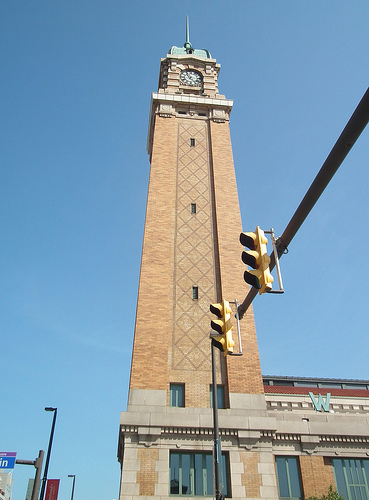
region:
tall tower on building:
[111, 8, 367, 498]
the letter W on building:
[298, 381, 336, 417]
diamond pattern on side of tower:
[173, 118, 222, 376]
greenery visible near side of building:
[300, 469, 343, 498]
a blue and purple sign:
[0, 441, 45, 498]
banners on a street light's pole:
[19, 400, 66, 499]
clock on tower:
[170, 60, 213, 98]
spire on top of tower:
[163, 13, 212, 65]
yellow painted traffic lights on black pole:
[205, 108, 349, 366]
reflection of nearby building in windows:
[161, 457, 195, 497]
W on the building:
[307, 385, 337, 419]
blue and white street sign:
[0, 455, 15, 477]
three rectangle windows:
[188, 132, 202, 307]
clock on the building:
[177, 68, 210, 88]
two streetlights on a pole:
[209, 218, 292, 364]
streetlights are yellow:
[186, 239, 300, 367]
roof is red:
[270, 380, 365, 395]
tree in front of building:
[294, 485, 353, 498]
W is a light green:
[311, 391, 329, 413]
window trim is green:
[332, 456, 366, 498]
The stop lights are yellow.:
[189, 219, 304, 363]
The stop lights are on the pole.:
[190, 212, 368, 361]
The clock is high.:
[156, 30, 231, 123]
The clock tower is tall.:
[140, 20, 271, 474]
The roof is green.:
[159, 37, 224, 77]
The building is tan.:
[144, 43, 275, 482]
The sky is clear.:
[11, 33, 129, 310]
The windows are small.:
[150, 32, 264, 495]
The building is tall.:
[143, 14, 338, 498]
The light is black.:
[28, 390, 60, 498]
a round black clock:
[177, 66, 206, 87]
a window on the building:
[272, 450, 309, 498]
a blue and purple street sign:
[0, 447, 20, 472]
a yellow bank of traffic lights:
[205, 296, 237, 356]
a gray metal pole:
[26, 447, 47, 499]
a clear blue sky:
[1, 0, 368, 499]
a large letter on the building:
[306, 387, 334, 414]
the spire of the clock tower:
[181, 10, 193, 47]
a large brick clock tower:
[124, 12, 272, 410]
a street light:
[43, 402, 58, 414]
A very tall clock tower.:
[86, 13, 294, 400]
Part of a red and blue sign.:
[1, 448, 18, 472]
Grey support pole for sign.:
[15, 447, 49, 499]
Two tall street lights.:
[36, 389, 89, 498]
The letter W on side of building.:
[309, 384, 337, 417]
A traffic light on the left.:
[201, 284, 249, 369]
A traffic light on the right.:
[235, 220, 295, 306]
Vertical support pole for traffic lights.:
[206, 302, 229, 498]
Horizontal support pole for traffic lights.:
[222, 137, 365, 345]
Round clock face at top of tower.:
[174, 63, 208, 96]